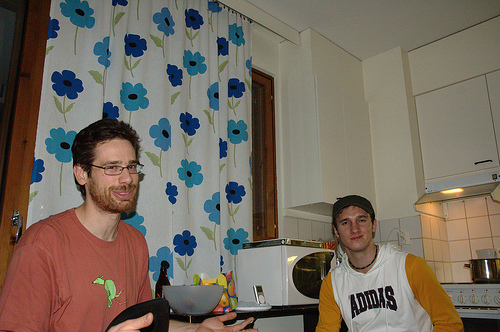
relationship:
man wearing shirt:
[312, 194, 469, 329] [319, 247, 462, 331]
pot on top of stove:
[466, 257, 499, 281] [437, 281, 499, 331]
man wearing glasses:
[2, 118, 260, 331] [80, 158, 142, 176]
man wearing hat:
[312, 194, 469, 329] [334, 195, 375, 219]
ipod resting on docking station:
[252, 285, 266, 304] [233, 300, 273, 310]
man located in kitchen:
[312, 194, 469, 329] [2, 2, 499, 330]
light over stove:
[441, 186, 465, 196] [437, 281, 499, 331]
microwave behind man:
[235, 247, 335, 303] [312, 194, 469, 329]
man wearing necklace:
[312, 194, 469, 329] [345, 246, 377, 269]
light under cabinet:
[441, 186, 465, 196] [412, 72, 498, 178]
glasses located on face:
[80, 158, 142, 176] [93, 144, 139, 210]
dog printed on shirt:
[92, 277, 123, 306] [1, 206, 152, 330]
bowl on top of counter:
[161, 284, 222, 315] [169, 306, 316, 331]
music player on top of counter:
[252, 285, 266, 304] [169, 306, 316, 331]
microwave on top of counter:
[235, 247, 335, 303] [169, 306, 316, 331]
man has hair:
[2, 118, 260, 331] [70, 119, 140, 191]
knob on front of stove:
[469, 294, 479, 305] [437, 281, 499, 331]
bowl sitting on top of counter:
[161, 284, 222, 315] [169, 306, 316, 331]